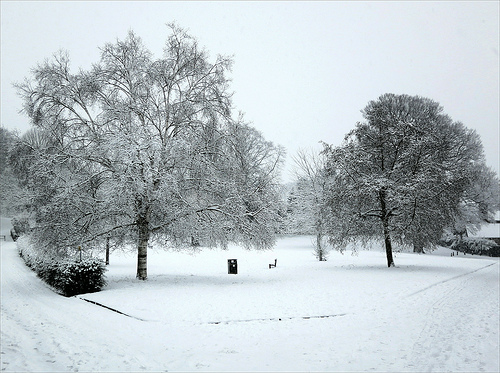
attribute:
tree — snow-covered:
[0, 31, 274, 292]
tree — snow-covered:
[326, 87, 495, 266]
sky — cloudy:
[6, 2, 499, 155]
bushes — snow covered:
[16, 226, 101, 287]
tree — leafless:
[1, 19, 281, 253]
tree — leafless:
[315, 94, 499, 268]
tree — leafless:
[293, 147, 341, 260]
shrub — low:
[18, 227, 100, 297]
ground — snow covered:
[20, 253, 480, 366]